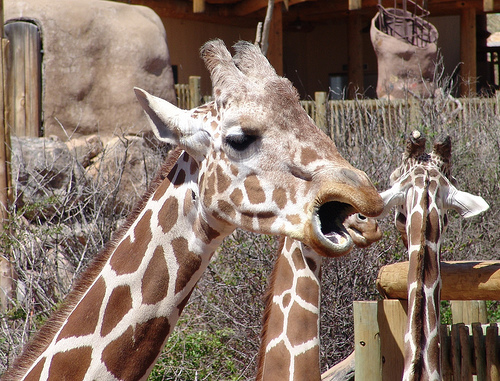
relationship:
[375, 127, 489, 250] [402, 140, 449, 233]
giraffe head has back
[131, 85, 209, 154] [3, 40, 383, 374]
ear on giraffe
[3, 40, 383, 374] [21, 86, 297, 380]
giraffe has spots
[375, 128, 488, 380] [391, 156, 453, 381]
giraffe has spots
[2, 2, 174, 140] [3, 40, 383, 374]
rock behind giraffe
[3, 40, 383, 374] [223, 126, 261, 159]
giraffe has eye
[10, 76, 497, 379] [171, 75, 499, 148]
enclosure has fence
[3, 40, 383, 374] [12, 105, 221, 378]
giraffe has neck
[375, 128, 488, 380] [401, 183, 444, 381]
giraffe has neck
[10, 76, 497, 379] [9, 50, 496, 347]
enclosure has branches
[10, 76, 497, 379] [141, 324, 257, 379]
enclosure has grass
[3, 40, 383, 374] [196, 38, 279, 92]
giraffe has ossicones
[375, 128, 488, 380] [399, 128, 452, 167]
giraffe has ossicones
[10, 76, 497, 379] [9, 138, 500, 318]
enclosure has wall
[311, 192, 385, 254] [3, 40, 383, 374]
open mouth on giraffe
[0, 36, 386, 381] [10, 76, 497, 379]
giraffe in enclosure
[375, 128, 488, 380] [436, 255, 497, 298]
giraffe has shadow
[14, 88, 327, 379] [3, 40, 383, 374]
brown spots on giraffe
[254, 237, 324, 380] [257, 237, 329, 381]
brown spots on giraffe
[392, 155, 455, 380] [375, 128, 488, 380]
brown spots on giraffe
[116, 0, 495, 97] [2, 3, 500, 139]
building in background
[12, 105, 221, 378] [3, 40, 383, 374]
neck on giraffe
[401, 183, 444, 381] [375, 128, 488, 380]
neck on giraffe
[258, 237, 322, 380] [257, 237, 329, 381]
neck on giraffe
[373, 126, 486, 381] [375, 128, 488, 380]
back view of giraffe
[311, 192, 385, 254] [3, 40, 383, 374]
mouth open on giraffe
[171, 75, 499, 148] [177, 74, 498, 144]
fence made of wood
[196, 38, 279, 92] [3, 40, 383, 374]
ossicones on giraffe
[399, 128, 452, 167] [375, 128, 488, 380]
ossicones on giraffe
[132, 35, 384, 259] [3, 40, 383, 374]
face on giraffe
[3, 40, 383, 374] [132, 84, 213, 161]
giraffe has ear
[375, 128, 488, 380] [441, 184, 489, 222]
giraffe has ear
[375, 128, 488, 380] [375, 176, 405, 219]
giraffe has ear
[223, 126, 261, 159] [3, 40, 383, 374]
black eye on giraffe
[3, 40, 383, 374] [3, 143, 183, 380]
giraffe has mane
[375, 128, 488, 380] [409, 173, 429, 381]
giraffe has mane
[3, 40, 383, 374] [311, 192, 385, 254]
giraffe has open mouth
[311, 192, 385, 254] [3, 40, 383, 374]
open mouth open giraffe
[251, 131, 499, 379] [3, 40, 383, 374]
two giraffes behind front giraffe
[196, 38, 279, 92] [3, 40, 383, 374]
two ossicones on giraffe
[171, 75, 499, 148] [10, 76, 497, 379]
fence in enclosure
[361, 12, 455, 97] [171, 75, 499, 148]
boulder behind fence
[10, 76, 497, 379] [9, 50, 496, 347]
enclosure has shrubs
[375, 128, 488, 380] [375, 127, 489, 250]
giraffe has back of head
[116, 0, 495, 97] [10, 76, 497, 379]
building back of enclosure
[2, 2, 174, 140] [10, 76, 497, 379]
stone in enclosure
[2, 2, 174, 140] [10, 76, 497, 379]
big stone in enclosure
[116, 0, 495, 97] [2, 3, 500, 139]
house in background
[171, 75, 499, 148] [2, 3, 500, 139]
wooden fence in background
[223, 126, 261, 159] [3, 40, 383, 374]
eye on giraffe